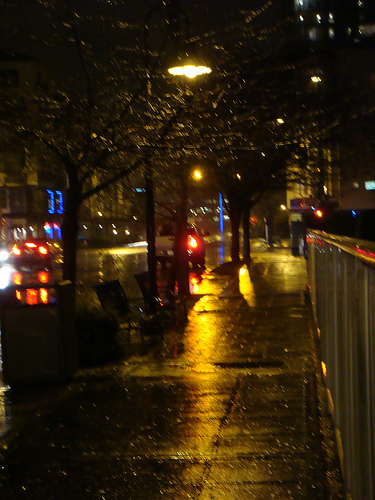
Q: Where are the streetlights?
A: Above the sidewalk.